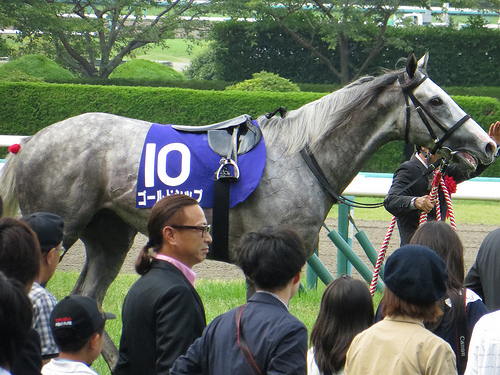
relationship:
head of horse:
[396, 48, 496, 173] [3, 47, 498, 372]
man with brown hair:
[115, 195, 213, 373] [130, 192, 199, 276]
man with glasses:
[115, 195, 213, 373] [173, 220, 213, 237]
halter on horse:
[413, 110, 440, 134] [359, 60, 468, 167]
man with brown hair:
[115, 195, 213, 373] [133, 196, 198, 278]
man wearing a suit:
[155, 225, 306, 375] [210, 288, 300, 370]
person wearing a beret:
[15, 209, 65, 364] [16, 211, 67, 250]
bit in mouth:
[444, 144, 457, 157] [448, 144, 484, 169]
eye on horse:
[428, 94, 443, 108] [3, 47, 498, 372]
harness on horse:
[134, 113, 266, 265] [11, 32, 483, 302]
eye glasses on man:
[171, 221, 212, 238] [107, 195, 215, 370]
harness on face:
[120, 99, 280, 259] [395, 56, 485, 157]